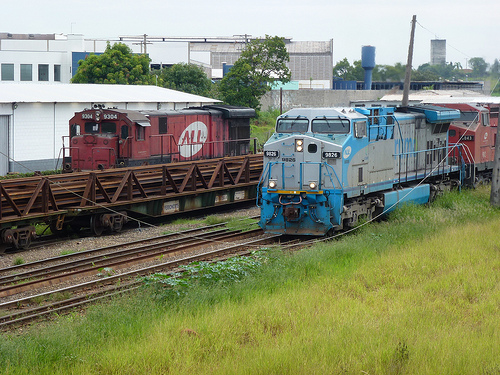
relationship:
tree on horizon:
[466, 55, 492, 74] [341, 50, 489, 74]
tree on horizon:
[332, 58, 354, 87] [341, 50, 489, 74]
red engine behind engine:
[440, 95, 498, 175] [258, 103, 462, 223]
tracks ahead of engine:
[1, 212, 261, 331] [258, 103, 462, 223]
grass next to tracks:
[4, 182, 499, 373] [1, 212, 261, 331]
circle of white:
[178, 119, 210, 160] [197, 124, 209, 141]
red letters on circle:
[181, 132, 206, 145] [178, 119, 210, 160]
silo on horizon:
[431, 39, 446, 69] [341, 50, 489, 74]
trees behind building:
[74, 36, 291, 109] [1, 84, 220, 170]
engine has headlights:
[258, 103, 462, 223] [267, 142, 318, 195]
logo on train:
[178, 119, 210, 160] [69, 105, 261, 169]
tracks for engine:
[1, 212, 261, 331] [69, 105, 261, 169]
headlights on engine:
[267, 142, 318, 195] [258, 103, 462, 223]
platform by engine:
[1, 154, 268, 232] [258, 103, 462, 223]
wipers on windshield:
[288, 117, 333, 134] [280, 117, 351, 137]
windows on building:
[4, 63, 59, 82] [5, 39, 76, 86]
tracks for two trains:
[1, 212, 261, 331] [66, 110, 452, 238]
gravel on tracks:
[1, 189, 267, 267] [1, 212, 261, 331]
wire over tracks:
[1, 98, 495, 243] [1, 212, 261, 331]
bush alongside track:
[152, 248, 280, 293] [1, 212, 261, 331]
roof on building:
[2, 80, 219, 105] [1, 84, 220, 170]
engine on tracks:
[258, 103, 462, 223] [1, 212, 261, 331]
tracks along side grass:
[1, 212, 261, 331] [4, 182, 499, 373]